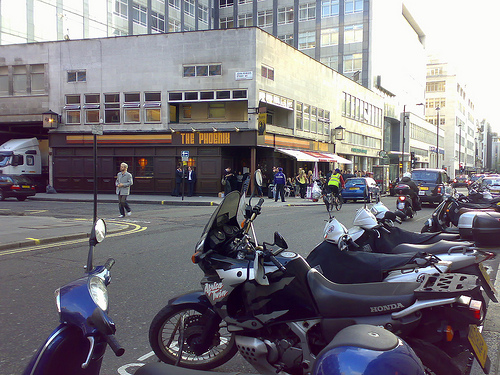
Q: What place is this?
A: It is a street.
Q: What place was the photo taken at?
A: It was taken at the street.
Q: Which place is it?
A: It is a street.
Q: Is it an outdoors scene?
A: Yes, it is outdoors.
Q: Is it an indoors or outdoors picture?
A: It is outdoors.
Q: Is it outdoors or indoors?
A: It is outdoors.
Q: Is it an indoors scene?
A: No, it is outdoors.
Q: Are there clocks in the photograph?
A: No, there are no clocks.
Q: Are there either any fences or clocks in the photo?
A: No, there are no clocks or fences.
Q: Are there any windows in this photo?
A: Yes, there are windows.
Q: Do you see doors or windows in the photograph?
A: Yes, there are windows.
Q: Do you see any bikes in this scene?
A: Yes, there is a bike.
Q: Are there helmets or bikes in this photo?
A: Yes, there is a bike.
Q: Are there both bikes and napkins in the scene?
A: No, there is a bike but no napkins.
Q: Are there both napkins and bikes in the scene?
A: No, there is a bike but no napkins.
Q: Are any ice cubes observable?
A: No, there are no ice cubes.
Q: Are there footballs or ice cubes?
A: No, there are no ice cubes or footballs.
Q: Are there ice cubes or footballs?
A: No, there are no ice cubes or footballs.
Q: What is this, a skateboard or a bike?
A: This is a bike.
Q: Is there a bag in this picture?
A: No, there are no bags.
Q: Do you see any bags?
A: No, there are no bags.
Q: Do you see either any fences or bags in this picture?
A: No, there are no bags or fences.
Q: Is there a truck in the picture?
A: Yes, there is a truck.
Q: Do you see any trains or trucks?
A: Yes, there is a truck.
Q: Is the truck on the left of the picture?
A: Yes, the truck is on the left of the image.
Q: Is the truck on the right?
A: No, the truck is on the left of the image.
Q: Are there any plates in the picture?
A: Yes, there is a plate.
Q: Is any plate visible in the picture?
A: Yes, there is a plate.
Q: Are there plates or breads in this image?
A: Yes, there is a plate.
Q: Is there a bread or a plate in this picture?
A: Yes, there is a plate.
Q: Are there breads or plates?
A: Yes, there is a plate.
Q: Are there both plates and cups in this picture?
A: No, there is a plate but no cups.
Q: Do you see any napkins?
A: No, there are no napkins.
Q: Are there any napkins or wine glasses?
A: No, there are no napkins or wine glasses.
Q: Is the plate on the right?
A: Yes, the plate is on the right of the image.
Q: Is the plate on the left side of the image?
A: No, the plate is on the right of the image.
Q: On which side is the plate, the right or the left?
A: The plate is on the right of the image.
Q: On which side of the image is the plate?
A: The plate is on the right of the image.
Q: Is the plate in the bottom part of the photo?
A: Yes, the plate is in the bottom of the image.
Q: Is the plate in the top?
A: No, the plate is in the bottom of the image.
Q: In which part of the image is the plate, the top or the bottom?
A: The plate is in the bottom of the image.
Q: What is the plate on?
A: The plate is on the bike.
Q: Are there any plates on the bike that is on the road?
A: Yes, there is a plate on the bike.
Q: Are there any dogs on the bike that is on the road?
A: No, there is a plate on the bike.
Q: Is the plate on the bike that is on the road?
A: Yes, the plate is on the bike.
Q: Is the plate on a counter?
A: No, the plate is on the bike.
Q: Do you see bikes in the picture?
A: Yes, there are bikes.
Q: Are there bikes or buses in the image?
A: Yes, there are bikes.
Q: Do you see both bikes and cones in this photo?
A: No, there are bikes but no cones.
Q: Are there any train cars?
A: No, there are no train cars.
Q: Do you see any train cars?
A: No, there are no train cars.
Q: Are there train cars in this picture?
A: No, there are no train cars.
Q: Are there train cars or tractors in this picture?
A: No, there are no train cars or tractors.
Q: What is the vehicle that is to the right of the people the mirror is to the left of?
A: The vehicle is a car.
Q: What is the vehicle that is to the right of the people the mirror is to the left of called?
A: The vehicle is a car.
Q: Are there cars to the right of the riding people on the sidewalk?
A: Yes, there is a car to the right of the people.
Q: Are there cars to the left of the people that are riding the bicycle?
A: No, the car is to the right of the people.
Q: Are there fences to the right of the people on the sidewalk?
A: No, there is a car to the right of the people.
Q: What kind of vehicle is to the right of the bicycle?
A: The vehicle is a car.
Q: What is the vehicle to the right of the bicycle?
A: The vehicle is a car.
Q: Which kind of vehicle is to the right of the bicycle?
A: The vehicle is a car.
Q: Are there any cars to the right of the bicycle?
A: Yes, there is a car to the right of the bicycle.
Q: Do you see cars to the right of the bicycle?
A: Yes, there is a car to the right of the bicycle.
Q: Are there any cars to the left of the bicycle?
A: No, the car is to the right of the bicycle.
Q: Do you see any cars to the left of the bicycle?
A: No, the car is to the right of the bicycle.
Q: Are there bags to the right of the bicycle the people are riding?
A: No, there is a car to the right of the bicycle.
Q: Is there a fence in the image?
A: No, there are no fences.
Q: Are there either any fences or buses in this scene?
A: No, there are no fences or buses.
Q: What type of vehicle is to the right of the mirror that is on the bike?
A: The vehicle is a car.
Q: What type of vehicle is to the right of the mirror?
A: The vehicle is a car.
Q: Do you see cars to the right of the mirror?
A: Yes, there is a car to the right of the mirror.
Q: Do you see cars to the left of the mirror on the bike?
A: No, the car is to the right of the mirror.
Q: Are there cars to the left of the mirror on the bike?
A: No, the car is to the right of the mirror.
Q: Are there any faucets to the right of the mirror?
A: No, there is a car to the right of the mirror.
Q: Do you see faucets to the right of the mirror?
A: No, there is a car to the right of the mirror.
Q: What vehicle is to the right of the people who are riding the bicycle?
A: The vehicle is a car.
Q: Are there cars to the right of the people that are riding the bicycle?
A: Yes, there is a car to the right of the people.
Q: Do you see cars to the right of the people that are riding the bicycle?
A: Yes, there is a car to the right of the people.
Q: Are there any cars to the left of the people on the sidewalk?
A: No, the car is to the right of the people.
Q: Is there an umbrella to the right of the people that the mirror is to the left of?
A: No, there is a car to the right of the people.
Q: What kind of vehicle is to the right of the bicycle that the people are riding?
A: The vehicle is a car.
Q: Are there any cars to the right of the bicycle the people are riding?
A: Yes, there is a car to the right of the bicycle.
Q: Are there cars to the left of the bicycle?
A: No, the car is to the right of the bicycle.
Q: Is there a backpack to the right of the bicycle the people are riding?
A: No, there is a car to the right of the bicycle.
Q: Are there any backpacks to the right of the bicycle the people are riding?
A: No, there is a car to the right of the bicycle.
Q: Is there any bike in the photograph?
A: Yes, there is a bike.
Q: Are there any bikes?
A: Yes, there is a bike.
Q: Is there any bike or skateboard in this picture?
A: Yes, there is a bike.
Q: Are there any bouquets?
A: No, there are no bouquets.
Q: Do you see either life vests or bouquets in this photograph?
A: No, there are no bouquets or life vests.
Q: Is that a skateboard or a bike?
A: That is a bike.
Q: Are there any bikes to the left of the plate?
A: Yes, there is a bike to the left of the plate.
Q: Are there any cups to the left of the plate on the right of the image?
A: No, there is a bike to the left of the plate.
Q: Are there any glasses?
A: No, there are no glasses.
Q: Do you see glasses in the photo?
A: No, there are no glasses.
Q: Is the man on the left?
A: Yes, the man is on the left of the image.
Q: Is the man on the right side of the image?
A: No, the man is on the left of the image.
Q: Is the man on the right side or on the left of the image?
A: The man is on the left of the image.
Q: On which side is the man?
A: The man is on the left of the image.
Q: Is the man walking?
A: Yes, the man is walking.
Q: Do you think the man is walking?
A: Yes, the man is walking.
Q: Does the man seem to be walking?
A: Yes, the man is walking.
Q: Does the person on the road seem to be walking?
A: Yes, the man is walking.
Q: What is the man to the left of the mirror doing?
A: The man is walking.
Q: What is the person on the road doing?
A: The man is walking.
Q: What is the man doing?
A: The man is walking.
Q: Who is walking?
A: The man is walking.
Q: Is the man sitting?
A: No, the man is walking.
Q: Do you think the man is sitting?
A: No, the man is walking.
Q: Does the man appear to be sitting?
A: No, the man is walking.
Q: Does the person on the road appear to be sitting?
A: No, the man is walking.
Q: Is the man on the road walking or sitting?
A: The man is walking.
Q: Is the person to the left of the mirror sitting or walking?
A: The man is walking.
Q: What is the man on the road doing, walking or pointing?
A: The man is walking.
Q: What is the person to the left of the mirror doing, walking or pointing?
A: The man is walking.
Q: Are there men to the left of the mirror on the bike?
A: Yes, there is a man to the left of the mirror.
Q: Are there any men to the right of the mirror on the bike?
A: No, the man is to the left of the mirror.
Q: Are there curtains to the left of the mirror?
A: No, there is a man to the left of the mirror.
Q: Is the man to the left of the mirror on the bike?
A: Yes, the man is to the left of the mirror.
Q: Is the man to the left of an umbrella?
A: No, the man is to the left of the mirror.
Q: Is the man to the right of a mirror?
A: No, the man is to the left of a mirror.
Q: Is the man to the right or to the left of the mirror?
A: The man is to the left of the mirror.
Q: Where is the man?
A: The man is on the road.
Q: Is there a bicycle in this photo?
A: Yes, there is a bicycle.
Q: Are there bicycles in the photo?
A: Yes, there is a bicycle.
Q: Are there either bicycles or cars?
A: Yes, there is a bicycle.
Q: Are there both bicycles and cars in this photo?
A: Yes, there are both a bicycle and a car.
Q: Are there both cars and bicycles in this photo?
A: Yes, there are both a bicycle and a car.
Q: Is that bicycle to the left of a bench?
A: No, the bicycle is to the left of the car.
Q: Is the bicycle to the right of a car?
A: No, the bicycle is to the left of a car.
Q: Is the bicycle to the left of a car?
A: Yes, the bicycle is to the left of a car.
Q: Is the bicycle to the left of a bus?
A: No, the bicycle is to the left of a car.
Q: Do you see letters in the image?
A: Yes, there are letters.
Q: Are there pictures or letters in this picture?
A: Yes, there are letters.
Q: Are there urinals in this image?
A: No, there are no urinals.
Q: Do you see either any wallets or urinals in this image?
A: No, there are no urinals or wallets.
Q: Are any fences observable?
A: No, there are no fences.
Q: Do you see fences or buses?
A: No, there are no fences or buses.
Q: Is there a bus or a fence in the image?
A: No, there are no fences or buses.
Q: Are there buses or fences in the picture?
A: No, there are no fences or buses.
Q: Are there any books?
A: No, there are no books.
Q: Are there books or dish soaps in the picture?
A: No, there are no books or dish soaps.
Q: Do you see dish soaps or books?
A: No, there are no books or dish soaps.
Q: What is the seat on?
A: The seat is on the bike.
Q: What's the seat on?
A: The seat is on the bike.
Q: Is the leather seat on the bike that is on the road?
A: Yes, the seat is on the bike.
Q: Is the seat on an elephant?
A: No, the seat is on the bike.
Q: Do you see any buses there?
A: No, there are no buses.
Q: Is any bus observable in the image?
A: No, there are no buses.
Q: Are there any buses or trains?
A: No, there are no buses or trains.